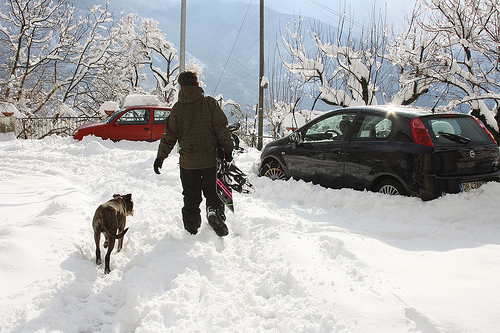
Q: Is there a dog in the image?
A: Yes, there is a dog.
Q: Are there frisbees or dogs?
A: Yes, there is a dog.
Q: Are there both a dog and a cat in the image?
A: No, there is a dog but no cats.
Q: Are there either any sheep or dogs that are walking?
A: Yes, the dog is walking.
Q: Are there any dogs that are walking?
A: Yes, there is a dog that is walking.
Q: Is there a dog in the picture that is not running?
A: Yes, there is a dog that is walking.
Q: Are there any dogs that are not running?
A: Yes, there is a dog that is walking.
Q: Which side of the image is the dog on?
A: The dog is on the left of the image.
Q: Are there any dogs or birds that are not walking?
A: No, there is a dog but it is walking.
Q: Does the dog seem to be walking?
A: Yes, the dog is walking.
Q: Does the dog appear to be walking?
A: Yes, the dog is walking.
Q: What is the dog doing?
A: The dog is walking.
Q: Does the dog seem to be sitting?
A: No, the dog is walking.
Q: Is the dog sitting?
A: No, the dog is walking.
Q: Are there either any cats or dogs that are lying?
A: No, there is a dog but it is walking.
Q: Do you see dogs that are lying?
A: No, there is a dog but it is walking.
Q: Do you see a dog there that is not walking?
A: No, there is a dog but it is walking.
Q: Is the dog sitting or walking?
A: The dog is walking.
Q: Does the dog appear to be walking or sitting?
A: The dog is walking.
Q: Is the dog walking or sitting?
A: The dog is walking.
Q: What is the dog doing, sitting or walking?
A: The dog is walking.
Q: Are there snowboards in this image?
A: Yes, there is a snowboard.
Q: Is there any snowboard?
A: Yes, there is a snowboard.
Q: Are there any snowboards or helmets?
A: Yes, there is a snowboard.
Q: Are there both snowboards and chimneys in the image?
A: No, there is a snowboard but no chimneys.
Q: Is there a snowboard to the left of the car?
A: Yes, there is a snowboard to the left of the car.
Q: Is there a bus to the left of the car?
A: No, there is a snowboard to the left of the car.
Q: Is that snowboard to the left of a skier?
A: No, the snowboard is to the left of the car.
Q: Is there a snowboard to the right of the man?
A: Yes, there is a snowboard to the right of the man.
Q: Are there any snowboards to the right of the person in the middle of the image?
A: Yes, there is a snowboard to the right of the man.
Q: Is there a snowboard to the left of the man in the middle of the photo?
A: No, the snowboard is to the right of the man.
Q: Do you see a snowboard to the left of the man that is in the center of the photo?
A: No, the snowboard is to the right of the man.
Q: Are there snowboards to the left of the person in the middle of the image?
A: No, the snowboard is to the right of the man.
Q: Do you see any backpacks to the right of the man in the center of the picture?
A: No, there is a snowboard to the right of the man.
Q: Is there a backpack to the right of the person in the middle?
A: No, there is a snowboard to the right of the man.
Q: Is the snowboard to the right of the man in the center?
A: Yes, the snowboard is to the right of the man.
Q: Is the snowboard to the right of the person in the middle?
A: Yes, the snowboard is to the right of the man.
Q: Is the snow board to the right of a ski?
A: No, the snow board is to the right of the man.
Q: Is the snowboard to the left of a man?
A: No, the snowboard is to the right of a man.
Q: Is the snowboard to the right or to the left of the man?
A: The snowboard is to the right of the man.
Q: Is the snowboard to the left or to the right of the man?
A: The snowboard is to the right of the man.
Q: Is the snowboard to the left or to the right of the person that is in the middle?
A: The snowboard is to the right of the man.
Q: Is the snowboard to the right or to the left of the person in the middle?
A: The snowboard is to the right of the man.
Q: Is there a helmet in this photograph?
A: No, there are no helmets.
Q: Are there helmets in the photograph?
A: No, there are no helmets.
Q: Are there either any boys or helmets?
A: No, there are no helmets or boys.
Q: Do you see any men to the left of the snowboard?
A: Yes, there is a man to the left of the snowboard.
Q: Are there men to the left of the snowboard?
A: Yes, there is a man to the left of the snowboard.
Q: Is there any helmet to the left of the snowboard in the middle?
A: No, there is a man to the left of the snow board.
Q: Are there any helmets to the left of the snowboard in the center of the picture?
A: No, there is a man to the left of the snow board.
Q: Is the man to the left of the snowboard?
A: Yes, the man is to the left of the snowboard.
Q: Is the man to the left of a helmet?
A: No, the man is to the left of the snowboard.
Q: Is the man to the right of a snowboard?
A: No, the man is to the left of a snowboard.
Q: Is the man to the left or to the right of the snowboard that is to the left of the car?
A: The man is to the left of the snowboard.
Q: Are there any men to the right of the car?
A: No, the man is to the left of the car.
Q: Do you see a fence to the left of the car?
A: No, there is a man to the left of the car.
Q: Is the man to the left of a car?
A: Yes, the man is to the left of a car.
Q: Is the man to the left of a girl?
A: No, the man is to the left of a car.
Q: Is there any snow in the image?
A: Yes, there is snow.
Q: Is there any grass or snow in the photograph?
A: Yes, there is snow.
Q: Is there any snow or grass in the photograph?
A: Yes, there is snow.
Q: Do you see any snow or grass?
A: Yes, there is snow.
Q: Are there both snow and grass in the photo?
A: No, there is snow but no grass.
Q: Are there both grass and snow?
A: No, there is snow but no grass.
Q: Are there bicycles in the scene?
A: No, there are no bicycles.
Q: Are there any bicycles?
A: No, there are no bicycles.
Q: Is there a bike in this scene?
A: No, there are no bikes.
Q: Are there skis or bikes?
A: No, there are no bikes or skis.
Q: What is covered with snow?
A: The trees are covered with snow.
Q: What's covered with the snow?
A: The trees are covered with snow.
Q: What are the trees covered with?
A: The trees are covered with snow.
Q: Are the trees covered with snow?
A: Yes, the trees are covered with snow.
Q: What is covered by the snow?
A: The trees are covered by the snow.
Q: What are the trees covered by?
A: The trees are covered by the snow.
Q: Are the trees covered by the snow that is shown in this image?
A: Yes, the trees are covered by the snow.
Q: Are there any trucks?
A: No, there are no trucks.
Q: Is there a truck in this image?
A: No, there are no trucks.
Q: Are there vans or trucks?
A: No, there are no trucks or vans.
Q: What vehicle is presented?
A: The vehicle is a car.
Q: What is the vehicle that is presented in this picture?
A: The vehicle is a car.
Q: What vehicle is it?
A: The vehicle is a car.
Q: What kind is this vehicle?
A: This is a car.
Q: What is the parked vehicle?
A: The vehicle is a car.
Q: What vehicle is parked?
A: The vehicle is a car.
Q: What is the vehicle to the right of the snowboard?
A: The vehicle is a car.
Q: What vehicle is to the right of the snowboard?
A: The vehicle is a car.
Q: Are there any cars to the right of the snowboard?
A: Yes, there is a car to the right of the snowboard.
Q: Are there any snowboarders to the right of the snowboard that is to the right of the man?
A: No, there is a car to the right of the snowboard.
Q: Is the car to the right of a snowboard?
A: Yes, the car is to the right of a snowboard.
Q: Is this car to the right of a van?
A: No, the car is to the right of a snowboard.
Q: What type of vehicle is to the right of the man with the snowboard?
A: The vehicle is a car.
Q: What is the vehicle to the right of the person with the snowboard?
A: The vehicle is a car.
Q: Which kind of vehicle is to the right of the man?
A: The vehicle is a car.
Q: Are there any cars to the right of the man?
A: Yes, there is a car to the right of the man.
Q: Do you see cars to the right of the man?
A: Yes, there is a car to the right of the man.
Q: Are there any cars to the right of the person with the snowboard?
A: Yes, there is a car to the right of the man.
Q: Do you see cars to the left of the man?
A: No, the car is to the right of the man.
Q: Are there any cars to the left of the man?
A: No, the car is to the right of the man.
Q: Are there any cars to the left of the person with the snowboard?
A: No, the car is to the right of the man.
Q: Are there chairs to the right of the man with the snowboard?
A: No, there is a car to the right of the man.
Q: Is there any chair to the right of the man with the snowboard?
A: No, there is a car to the right of the man.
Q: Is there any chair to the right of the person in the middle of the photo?
A: No, there is a car to the right of the man.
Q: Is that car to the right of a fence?
A: No, the car is to the right of the man.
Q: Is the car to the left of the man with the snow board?
A: No, the car is to the right of the man.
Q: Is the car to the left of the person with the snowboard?
A: No, the car is to the right of the man.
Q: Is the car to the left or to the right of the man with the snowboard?
A: The car is to the right of the man.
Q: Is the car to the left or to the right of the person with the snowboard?
A: The car is to the right of the man.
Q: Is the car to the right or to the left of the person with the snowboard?
A: The car is to the right of the man.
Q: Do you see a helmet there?
A: No, there are no helmets.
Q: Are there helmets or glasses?
A: No, there are no helmets or glasses.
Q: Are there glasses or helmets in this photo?
A: No, there are no helmets or glasses.